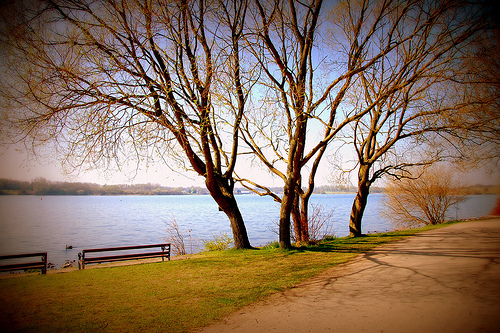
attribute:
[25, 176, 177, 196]
foot hills — small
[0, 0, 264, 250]
tree — leafless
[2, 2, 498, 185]
sky — blue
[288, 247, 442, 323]
road — dirt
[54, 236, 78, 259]
duck — floating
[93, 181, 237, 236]
water — large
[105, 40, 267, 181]
branches — Bare 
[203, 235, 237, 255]
shrub — small, green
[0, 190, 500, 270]
lake — blue 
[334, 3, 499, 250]
tree — small